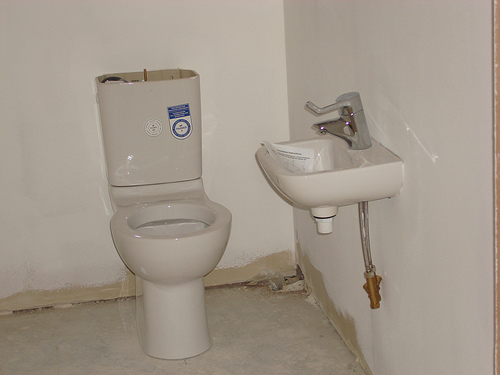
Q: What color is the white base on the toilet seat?
A: White.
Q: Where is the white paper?
A: In the bathroom sink.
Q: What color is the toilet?
A: White.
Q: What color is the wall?
A: White.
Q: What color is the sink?
A: White.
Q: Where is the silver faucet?
A: On the sink.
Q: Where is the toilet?
A: On the floor.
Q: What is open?
A: The toilet.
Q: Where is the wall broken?
A: In the corner.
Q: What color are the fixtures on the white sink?
A: Silver.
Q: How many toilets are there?
A: One.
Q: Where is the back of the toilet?
A: Against the wall.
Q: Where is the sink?
A: To the right of the toilet.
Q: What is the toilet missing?
A: The lid.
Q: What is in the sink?
A: Paper.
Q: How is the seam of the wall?
A: Cracked.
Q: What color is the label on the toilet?
A: Blue.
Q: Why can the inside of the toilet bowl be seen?
A: The lid is missing.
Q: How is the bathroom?
A: In need of repairs.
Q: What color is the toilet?
A: White.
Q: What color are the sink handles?
A: Silver.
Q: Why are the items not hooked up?
A: Unfinished bathroom.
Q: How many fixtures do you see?
A: Two.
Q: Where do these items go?
A: In a bathroom.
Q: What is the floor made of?
A: Concrete.